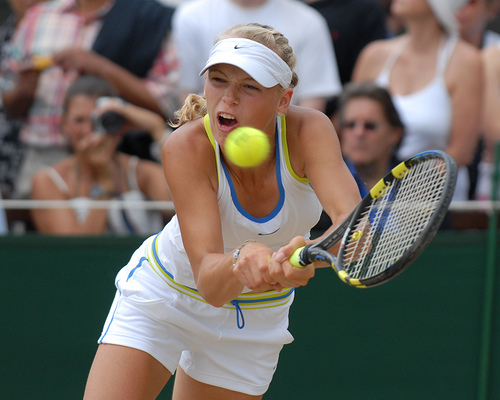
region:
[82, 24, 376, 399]
Woman wearing white tank top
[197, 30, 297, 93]
White sun visor on woman's head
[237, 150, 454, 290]
Tennis racket in woman's hands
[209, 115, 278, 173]
Tennis ball in the air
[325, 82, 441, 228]
Man wearing a blue shirt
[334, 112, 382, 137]
Glasses on man's face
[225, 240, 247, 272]
Bracelet on woman's arm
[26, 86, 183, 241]
Woman wearing white tank top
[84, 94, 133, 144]
Camera in woman's hands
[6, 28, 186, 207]
Man wearing a plaid shirt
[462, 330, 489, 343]
part of a wall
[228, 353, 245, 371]
part of a short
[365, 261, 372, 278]
part of a racket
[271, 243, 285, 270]
part of a shirt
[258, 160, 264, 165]
part of a ball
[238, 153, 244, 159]
part of a ball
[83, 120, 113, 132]
part of a camera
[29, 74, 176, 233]
female spectator taking pictures with her camera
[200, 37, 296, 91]
white Nike sports visor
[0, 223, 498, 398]
green boundary fence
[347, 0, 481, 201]
female spectator wearing a white tank top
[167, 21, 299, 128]
tennis players blonde braided hair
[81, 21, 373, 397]
young female tennis player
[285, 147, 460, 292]
black and yellow tennis racket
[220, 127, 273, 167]
yellow tennis ball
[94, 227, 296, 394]
white tennis shorts with blue and yellow stripes at waistband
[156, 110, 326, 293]
white tank top with blue and white edging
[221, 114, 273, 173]
the ball is yellow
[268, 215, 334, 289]
she is holding the racket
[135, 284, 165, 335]
the shorts are white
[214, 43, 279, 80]
the visor is white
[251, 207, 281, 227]
the neckline is blue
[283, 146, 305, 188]
the sleeve line is lime green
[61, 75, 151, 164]
the person is taking a picture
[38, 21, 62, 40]
the shirt is plaid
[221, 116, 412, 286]
she is hitting the ball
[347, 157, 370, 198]
the shirt is blue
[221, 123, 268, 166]
tennis ball in the air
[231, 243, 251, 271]
bracelet on a female tennis player's wrist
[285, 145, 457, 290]
black yellow and blue tennis racket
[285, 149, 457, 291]
tennis racket in the female player's hands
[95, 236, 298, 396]
white shorts on a female tennis player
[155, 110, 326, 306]
white blue and green top on a female player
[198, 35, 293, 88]
white visor on the tennis player's head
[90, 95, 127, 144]
black camera in a woman's hand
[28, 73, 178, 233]
woman taking a photo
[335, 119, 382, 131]
dark glasses over a man's eyes